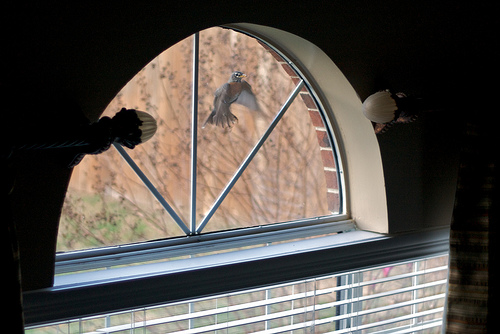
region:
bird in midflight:
[207, 70, 261, 125]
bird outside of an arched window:
[48, 23, 390, 253]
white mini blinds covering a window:
[243, 292, 433, 327]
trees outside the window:
[258, 156, 326, 214]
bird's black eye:
[233, 71, 239, 77]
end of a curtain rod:
[69, 107, 165, 146]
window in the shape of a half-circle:
[48, 21, 358, 251]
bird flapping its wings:
[203, 69, 260, 128]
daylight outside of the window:
[267, 160, 316, 205]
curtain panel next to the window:
[446, 90, 495, 331]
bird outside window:
[208, 70, 261, 134]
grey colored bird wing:
[210, 80, 240, 128]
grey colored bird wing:
[240, 85, 256, 105]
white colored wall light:
[355, 85, 420, 135]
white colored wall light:
[110, 105, 156, 145]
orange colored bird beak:
[235, 72, 246, 78]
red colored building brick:
[297, 90, 314, 107]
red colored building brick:
[313, 130, 333, 147]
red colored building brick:
[323, 170, 338, 188]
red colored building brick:
[324, 190, 340, 211]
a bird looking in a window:
[194, 65, 280, 143]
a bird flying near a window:
[202, 54, 280, 161]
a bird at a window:
[198, 60, 283, 147]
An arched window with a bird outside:
[37, 19, 404, 283]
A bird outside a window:
[155, 65, 297, 154]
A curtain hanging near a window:
[437, 45, 496, 332]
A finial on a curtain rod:
[351, 75, 481, 138]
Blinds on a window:
[18, 262, 478, 332]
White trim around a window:
[34, 213, 473, 325]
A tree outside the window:
[42, 64, 371, 249]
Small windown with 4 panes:
[65, 26, 418, 320]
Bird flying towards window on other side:
[195, 76, 277, 142]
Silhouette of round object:
[62, 105, 152, 170]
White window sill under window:
[38, 220, 377, 273]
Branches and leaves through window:
[85, 37, 338, 234]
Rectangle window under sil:
[63, 253, 446, 333]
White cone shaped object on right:
[355, 77, 398, 137]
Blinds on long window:
[0, 256, 459, 330]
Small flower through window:
[377, 260, 396, 277]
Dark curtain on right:
[423, 96, 498, 319]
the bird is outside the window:
[204, 57, 265, 134]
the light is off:
[357, 85, 406, 132]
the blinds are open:
[361, 279, 404, 316]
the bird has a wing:
[244, 84, 261, 113]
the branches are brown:
[77, 192, 131, 236]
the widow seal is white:
[186, 246, 251, 266]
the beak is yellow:
[238, 70, 248, 81]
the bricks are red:
[316, 132, 336, 198]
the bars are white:
[150, 190, 238, 231]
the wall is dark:
[21, 92, 51, 133]